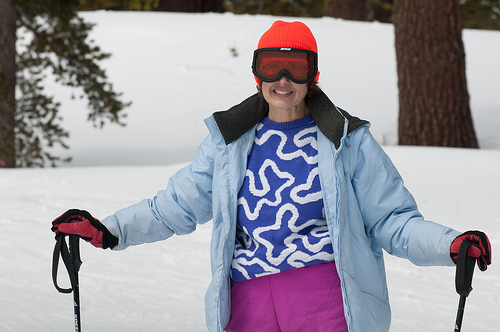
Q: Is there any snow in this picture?
A: Yes, there is snow.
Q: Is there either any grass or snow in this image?
A: Yes, there is snow.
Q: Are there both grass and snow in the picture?
A: No, there is snow but no grass.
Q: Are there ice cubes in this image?
A: No, there are no ice cubes.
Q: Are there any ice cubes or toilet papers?
A: No, there are no ice cubes or toilet papers.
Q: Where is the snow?
A: The snow is on the ground.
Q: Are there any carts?
A: No, there are no carts.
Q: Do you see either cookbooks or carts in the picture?
A: No, there are no carts or cookbooks.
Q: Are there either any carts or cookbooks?
A: No, there are no carts or cookbooks.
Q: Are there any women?
A: Yes, there is a woman.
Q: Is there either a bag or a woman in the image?
A: Yes, there is a woman.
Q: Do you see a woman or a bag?
A: Yes, there is a woman.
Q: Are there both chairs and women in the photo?
A: No, there is a woman but no chairs.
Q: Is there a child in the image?
A: No, there are no children.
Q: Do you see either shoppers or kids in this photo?
A: No, there are no kids or shoppers.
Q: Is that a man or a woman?
A: That is a woman.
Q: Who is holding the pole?
A: The woman is holding the pole.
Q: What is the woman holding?
A: The woman is holding the pole.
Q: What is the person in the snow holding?
A: The woman is holding the pole.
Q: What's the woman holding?
A: The woman is holding the pole.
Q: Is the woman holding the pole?
A: Yes, the woman is holding the pole.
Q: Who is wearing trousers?
A: The woman is wearing trousers.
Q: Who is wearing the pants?
A: The woman is wearing trousers.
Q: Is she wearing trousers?
A: Yes, the woman is wearing trousers.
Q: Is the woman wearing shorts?
A: No, the woman is wearing trousers.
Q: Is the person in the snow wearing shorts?
A: No, the woman is wearing trousers.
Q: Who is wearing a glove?
A: The woman is wearing a glove.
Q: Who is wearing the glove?
A: The woman is wearing a glove.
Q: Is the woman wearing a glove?
A: Yes, the woman is wearing a glove.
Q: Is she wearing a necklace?
A: No, the woman is wearing a glove.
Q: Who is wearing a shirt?
A: The woman is wearing a shirt.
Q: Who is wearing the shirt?
A: The woman is wearing a shirt.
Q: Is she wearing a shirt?
A: Yes, the woman is wearing a shirt.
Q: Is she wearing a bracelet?
A: No, the woman is wearing a shirt.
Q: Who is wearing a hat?
A: The woman is wearing a hat.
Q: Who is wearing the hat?
A: The woman is wearing a hat.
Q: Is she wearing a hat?
A: Yes, the woman is wearing a hat.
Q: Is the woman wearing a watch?
A: No, the woman is wearing a hat.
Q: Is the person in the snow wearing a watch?
A: No, the woman is wearing a hat.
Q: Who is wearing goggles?
A: The woman is wearing goggles.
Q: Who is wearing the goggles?
A: The woman is wearing goggles.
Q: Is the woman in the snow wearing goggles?
A: Yes, the woman is wearing goggles.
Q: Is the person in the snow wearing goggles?
A: Yes, the woman is wearing goggles.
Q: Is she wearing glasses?
A: No, the woman is wearing goggles.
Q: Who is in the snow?
A: The woman is in the snow.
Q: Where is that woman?
A: The woman is in the snow.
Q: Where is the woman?
A: The woman is in the snow.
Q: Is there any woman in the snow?
A: Yes, there is a woman in the snow.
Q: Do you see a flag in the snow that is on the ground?
A: No, there is a woman in the snow.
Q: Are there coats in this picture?
A: Yes, there is a coat.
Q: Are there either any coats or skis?
A: Yes, there is a coat.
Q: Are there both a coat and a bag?
A: No, there is a coat but no bags.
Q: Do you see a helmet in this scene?
A: No, there are no helmets.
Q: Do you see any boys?
A: No, there are no boys.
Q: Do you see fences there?
A: No, there are no fences.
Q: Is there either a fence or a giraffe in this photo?
A: No, there are no fences or giraffes.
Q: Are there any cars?
A: No, there are no cars.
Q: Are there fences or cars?
A: No, there are no cars or fences.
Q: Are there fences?
A: No, there are no fences.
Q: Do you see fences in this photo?
A: No, there are no fences.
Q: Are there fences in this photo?
A: No, there are no fences.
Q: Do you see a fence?
A: No, there are no fences.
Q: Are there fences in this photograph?
A: No, there are no fences.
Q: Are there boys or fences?
A: No, there are no fences or boys.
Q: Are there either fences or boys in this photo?
A: No, there are no fences or boys.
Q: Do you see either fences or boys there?
A: No, there are no fences or boys.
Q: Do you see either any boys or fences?
A: No, there are no fences or boys.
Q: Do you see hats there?
A: Yes, there is a hat.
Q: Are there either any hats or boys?
A: Yes, there is a hat.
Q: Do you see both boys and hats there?
A: No, there is a hat but no boys.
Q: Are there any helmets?
A: No, there are no helmets.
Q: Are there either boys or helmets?
A: No, there are no helmets or boys.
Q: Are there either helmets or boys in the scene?
A: No, there are no helmets or boys.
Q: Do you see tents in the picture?
A: No, there are no tents.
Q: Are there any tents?
A: No, there are no tents.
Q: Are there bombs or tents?
A: No, there are no tents or bombs.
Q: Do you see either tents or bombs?
A: No, there are no tents or bombs.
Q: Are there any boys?
A: No, there are no boys.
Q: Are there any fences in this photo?
A: No, there are no fences.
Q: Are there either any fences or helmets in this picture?
A: No, there are no fences or helmets.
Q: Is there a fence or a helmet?
A: No, there are no fences or helmets.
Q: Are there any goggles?
A: Yes, there are goggles.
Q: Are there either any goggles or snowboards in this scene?
A: Yes, there are goggles.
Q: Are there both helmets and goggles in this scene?
A: No, there are goggles but no helmets.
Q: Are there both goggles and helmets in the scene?
A: No, there are goggles but no helmets.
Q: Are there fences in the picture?
A: No, there are no fences.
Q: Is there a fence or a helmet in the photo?
A: No, there are no fences or helmets.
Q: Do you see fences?
A: No, there are no fences.